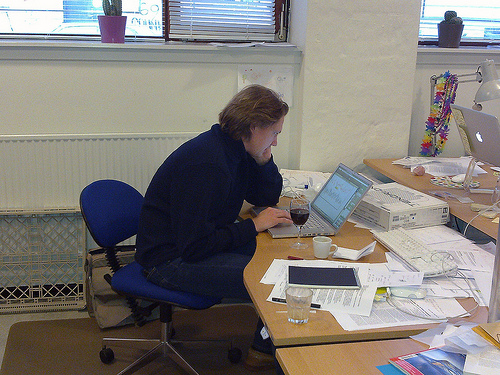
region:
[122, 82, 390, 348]
Man working on laptop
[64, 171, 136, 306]
Royal blue desk chair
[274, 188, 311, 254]
Red glass of wine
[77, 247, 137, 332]
Beige messenger bag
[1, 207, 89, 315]
White baby gate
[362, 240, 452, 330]
Assorted white papers on desk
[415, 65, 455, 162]
Flower necklace on lamp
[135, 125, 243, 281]
Dark blue pullover sweater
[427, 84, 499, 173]
Silver Apple laptop with sticky notes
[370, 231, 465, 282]
White keyboard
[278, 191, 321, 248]
a glass of red wine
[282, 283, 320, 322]
an empty glass cup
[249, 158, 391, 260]
the laptop is on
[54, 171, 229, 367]
blue office chair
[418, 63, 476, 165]
necklaces on the lamp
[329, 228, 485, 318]
papers scattered on the desk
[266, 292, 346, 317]
pens on the desk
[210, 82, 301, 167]
brown hair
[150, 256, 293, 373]
man wearing jeans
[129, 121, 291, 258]
man wearing a dark blue sweater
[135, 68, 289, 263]
A man with dark hair.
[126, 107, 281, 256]
A dark long sleeve top.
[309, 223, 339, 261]
A white coffee cup.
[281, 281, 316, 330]
A small clear glass.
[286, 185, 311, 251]
A glass of wine.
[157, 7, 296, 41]
Blinds on a window.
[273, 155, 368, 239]
An open laptop.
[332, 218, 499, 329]
Papers scattered on a desk.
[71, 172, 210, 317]
A blue computer chair.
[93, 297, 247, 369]
Swivel wheel base of chair.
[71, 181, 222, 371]
A BLUE COMPUTER CHAIR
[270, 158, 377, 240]
A GRAY LAPTOP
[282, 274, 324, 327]
AN EMPTY GLASS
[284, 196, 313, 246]
A GLASS OF RED WINE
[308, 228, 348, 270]
A WHITE COFFEE CUP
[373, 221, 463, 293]
A WHITE COMPUTER KEYBOARD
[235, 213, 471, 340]
A BROWN WOODEN TABLE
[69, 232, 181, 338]
A GRAY BAG ON THE FLOOR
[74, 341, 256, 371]
BLACK CHAIR WHEELS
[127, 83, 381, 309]
A MAN ON A LAPTOP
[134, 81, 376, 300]
Man working with his laptop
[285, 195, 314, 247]
Half full glass sitting on desk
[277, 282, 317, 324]
Empty glass sitting on desk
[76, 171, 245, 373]
Blue office chair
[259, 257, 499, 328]
Papers laying on desk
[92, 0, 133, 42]
Cactus in pink pot sitting on ledge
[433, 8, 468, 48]
Cactus in brown pot sitting on ledge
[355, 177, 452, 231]
Box laying on desk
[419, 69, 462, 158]
Hawaiian leis hanging on desk lamp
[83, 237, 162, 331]
Tan case sitting on floor